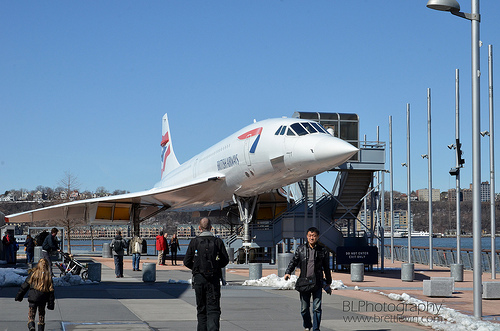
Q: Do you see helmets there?
A: No, there are no helmets.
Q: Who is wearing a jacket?
A: The man is wearing a jacket.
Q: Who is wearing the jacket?
A: The man is wearing a jacket.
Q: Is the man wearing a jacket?
A: Yes, the man is wearing a jacket.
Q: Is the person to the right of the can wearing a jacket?
A: Yes, the man is wearing a jacket.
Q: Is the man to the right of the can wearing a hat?
A: No, the man is wearing a jacket.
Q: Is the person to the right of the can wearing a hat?
A: No, the man is wearing a jacket.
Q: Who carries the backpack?
A: The man carries the backpack.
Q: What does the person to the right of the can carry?
A: The man carries a backpack.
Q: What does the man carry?
A: The man carries a backpack.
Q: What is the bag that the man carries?
A: The bag is a backpack.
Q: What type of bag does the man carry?
A: The man carries a backpack.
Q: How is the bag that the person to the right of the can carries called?
A: The bag is a backpack.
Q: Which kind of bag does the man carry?
A: The man carries a backpack.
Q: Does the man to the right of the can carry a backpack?
A: Yes, the man carries a backpack.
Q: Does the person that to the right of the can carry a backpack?
A: Yes, the man carries a backpack.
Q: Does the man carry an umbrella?
A: No, the man carries a backpack.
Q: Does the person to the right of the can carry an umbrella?
A: No, the man carries a backpack.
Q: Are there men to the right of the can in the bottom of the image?
A: Yes, there is a man to the right of the can.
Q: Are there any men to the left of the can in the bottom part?
A: No, the man is to the right of the can.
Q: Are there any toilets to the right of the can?
A: No, there is a man to the right of the can.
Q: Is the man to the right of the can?
A: Yes, the man is to the right of the can.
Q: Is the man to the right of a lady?
A: No, the man is to the right of the can.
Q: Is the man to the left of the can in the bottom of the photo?
A: No, the man is to the right of the can.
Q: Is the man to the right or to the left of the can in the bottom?
A: The man is to the right of the can.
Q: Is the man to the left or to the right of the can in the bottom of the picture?
A: The man is to the right of the can.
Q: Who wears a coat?
A: The man wears a coat.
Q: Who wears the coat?
A: The man wears a coat.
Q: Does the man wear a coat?
A: Yes, the man wears a coat.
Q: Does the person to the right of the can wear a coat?
A: Yes, the man wears a coat.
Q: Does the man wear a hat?
A: No, the man wears a coat.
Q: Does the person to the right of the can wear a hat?
A: No, the man wears a coat.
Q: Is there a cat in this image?
A: No, there are no cats.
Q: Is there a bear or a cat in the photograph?
A: No, there are no cats or bears.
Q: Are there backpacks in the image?
A: Yes, there is a backpack.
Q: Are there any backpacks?
A: Yes, there is a backpack.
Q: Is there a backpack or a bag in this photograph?
A: Yes, there is a backpack.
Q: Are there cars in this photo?
A: No, there are no cars.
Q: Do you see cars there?
A: No, there are no cars.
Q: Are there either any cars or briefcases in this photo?
A: No, there are no cars or briefcases.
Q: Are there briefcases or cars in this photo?
A: No, there are no cars or briefcases.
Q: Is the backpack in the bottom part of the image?
A: Yes, the backpack is in the bottom of the image.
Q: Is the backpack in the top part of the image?
A: No, the backpack is in the bottom of the image.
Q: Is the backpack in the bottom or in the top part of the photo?
A: The backpack is in the bottom of the image.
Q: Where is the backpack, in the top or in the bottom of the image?
A: The backpack is in the bottom of the image.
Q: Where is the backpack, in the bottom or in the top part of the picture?
A: The backpack is in the bottom of the image.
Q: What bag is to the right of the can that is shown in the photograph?
A: The bag is a backpack.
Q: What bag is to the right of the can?
A: The bag is a backpack.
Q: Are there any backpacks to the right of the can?
A: Yes, there is a backpack to the right of the can.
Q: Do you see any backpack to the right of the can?
A: Yes, there is a backpack to the right of the can.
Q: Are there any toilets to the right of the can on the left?
A: No, there is a backpack to the right of the can.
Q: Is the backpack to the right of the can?
A: Yes, the backpack is to the right of the can.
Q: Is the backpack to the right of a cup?
A: No, the backpack is to the right of the can.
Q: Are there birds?
A: No, there are no birds.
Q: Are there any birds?
A: No, there are no birds.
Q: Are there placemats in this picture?
A: No, there are no placemats.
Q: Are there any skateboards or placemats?
A: No, there are no placemats or skateboards.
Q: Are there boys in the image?
A: No, there are no boys.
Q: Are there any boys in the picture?
A: No, there are no boys.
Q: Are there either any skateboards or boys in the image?
A: No, there are no boys or skateboards.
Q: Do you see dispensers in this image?
A: No, there are no dispensers.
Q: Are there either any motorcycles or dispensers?
A: No, there are no dispensers or motorcycles.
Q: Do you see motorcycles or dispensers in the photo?
A: No, there are no dispensers or motorcycles.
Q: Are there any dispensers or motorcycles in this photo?
A: No, there are no dispensers or motorcycles.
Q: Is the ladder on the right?
A: Yes, the ladder is on the right of the image.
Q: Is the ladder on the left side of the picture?
A: No, the ladder is on the right of the image.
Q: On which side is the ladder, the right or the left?
A: The ladder is on the right of the image.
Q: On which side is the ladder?
A: The ladder is on the right of the image.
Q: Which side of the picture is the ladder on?
A: The ladder is on the right of the image.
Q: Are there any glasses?
A: No, there are no glasses.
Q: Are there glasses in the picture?
A: No, there are no glasses.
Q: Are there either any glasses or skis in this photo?
A: No, there are no glasses or skis.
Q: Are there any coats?
A: Yes, there is a coat.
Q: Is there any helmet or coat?
A: Yes, there is a coat.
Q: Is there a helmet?
A: No, there are no helmets.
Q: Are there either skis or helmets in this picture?
A: No, there are no helmets or skis.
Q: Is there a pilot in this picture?
A: No, there are no pilots.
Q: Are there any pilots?
A: No, there are no pilots.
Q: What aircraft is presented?
A: The aircraft is a jet.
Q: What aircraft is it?
A: The aircraft is a jet.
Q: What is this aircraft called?
A: This is a jet.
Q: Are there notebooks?
A: No, there are no notebooks.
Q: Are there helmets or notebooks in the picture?
A: No, there are no notebooks or helmets.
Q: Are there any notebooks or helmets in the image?
A: No, there are no notebooks or helmets.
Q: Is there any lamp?
A: Yes, there is a lamp.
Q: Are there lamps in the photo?
A: Yes, there is a lamp.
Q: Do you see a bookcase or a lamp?
A: Yes, there is a lamp.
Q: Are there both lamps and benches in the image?
A: No, there is a lamp but no benches.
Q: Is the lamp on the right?
A: Yes, the lamp is on the right of the image.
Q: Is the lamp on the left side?
A: No, the lamp is on the right of the image.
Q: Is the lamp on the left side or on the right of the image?
A: The lamp is on the right of the image.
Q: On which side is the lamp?
A: The lamp is on the right of the image.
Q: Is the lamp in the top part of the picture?
A: Yes, the lamp is in the top of the image.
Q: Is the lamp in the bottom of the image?
A: No, the lamp is in the top of the image.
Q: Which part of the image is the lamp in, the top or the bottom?
A: The lamp is in the top of the image.